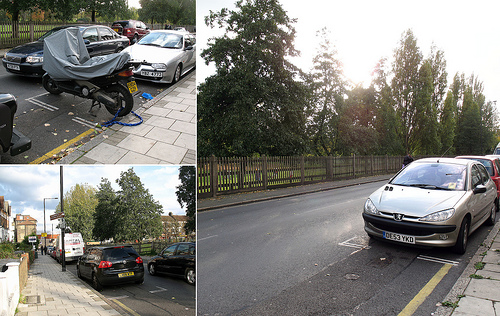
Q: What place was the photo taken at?
A: It was taken at the road.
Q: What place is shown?
A: It is a road.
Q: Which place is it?
A: It is a road.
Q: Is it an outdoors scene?
A: Yes, it is outdoors.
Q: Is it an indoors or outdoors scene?
A: It is outdoors.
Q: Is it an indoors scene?
A: No, it is outdoors.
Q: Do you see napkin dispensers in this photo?
A: No, there are no napkin dispensers.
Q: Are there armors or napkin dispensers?
A: No, there are no napkin dispensers or armors.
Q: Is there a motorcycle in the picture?
A: Yes, there is a motorcycle.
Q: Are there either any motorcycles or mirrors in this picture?
A: Yes, there is a motorcycle.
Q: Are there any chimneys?
A: No, there are no chimneys.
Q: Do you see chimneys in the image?
A: No, there are no chimneys.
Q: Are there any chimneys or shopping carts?
A: No, there are no chimneys or shopping carts.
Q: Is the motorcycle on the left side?
A: Yes, the motorcycle is on the left of the image.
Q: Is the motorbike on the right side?
A: No, the motorbike is on the left of the image.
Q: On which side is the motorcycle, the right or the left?
A: The motorcycle is on the left of the image.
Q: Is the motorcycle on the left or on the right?
A: The motorcycle is on the left of the image.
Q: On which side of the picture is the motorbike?
A: The motorbike is on the left of the image.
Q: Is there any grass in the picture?
A: Yes, there is grass.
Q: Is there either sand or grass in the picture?
A: Yes, there is grass.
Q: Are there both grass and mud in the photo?
A: No, there is grass but no mud.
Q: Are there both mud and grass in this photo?
A: No, there is grass but no mud.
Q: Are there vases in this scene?
A: No, there are no vases.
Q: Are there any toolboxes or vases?
A: No, there are no vases or toolboxes.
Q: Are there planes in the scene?
A: No, there are no planes.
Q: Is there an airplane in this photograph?
A: No, there are no airplanes.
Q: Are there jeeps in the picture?
A: No, there are no jeeps.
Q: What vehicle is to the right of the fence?
A: The vehicle is a car.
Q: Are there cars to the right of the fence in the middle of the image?
A: Yes, there is a car to the right of the fence.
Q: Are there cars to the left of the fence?
A: No, the car is to the right of the fence.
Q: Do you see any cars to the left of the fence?
A: No, the car is to the right of the fence.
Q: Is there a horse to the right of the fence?
A: No, there is a car to the right of the fence.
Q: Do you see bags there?
A: No, there are no bags.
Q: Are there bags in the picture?
A: No, there are no bags.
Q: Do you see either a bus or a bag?
A: No, there are no bags or buses.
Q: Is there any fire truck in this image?
A: No, there are no fire trucks.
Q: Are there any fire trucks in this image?
A: No, there are no fire trucks.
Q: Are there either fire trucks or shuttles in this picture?
A: No, there are no fire trucks or shuttles.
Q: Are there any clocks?
A: No, there are no clocks.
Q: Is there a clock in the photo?
A: No, there are no clocks.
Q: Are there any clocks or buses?
A: No, there are no clocks or buses.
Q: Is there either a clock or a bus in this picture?
A: No, there are no clocks or buses.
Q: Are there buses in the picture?
A: No, there are no buses.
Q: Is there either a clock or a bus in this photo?
A: No, there are no buses or clocks.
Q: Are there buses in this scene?
A: No, there are no buses.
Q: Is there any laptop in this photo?
A: No, there are no laptops.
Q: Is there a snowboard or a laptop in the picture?
A: No, there are no laptops or snowboards.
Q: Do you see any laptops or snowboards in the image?
A: No, there are no laptops or snowboards.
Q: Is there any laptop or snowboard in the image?
A: No, there are no laptops or snowboards.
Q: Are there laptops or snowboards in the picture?
A: No, there are no laptops or snowboards.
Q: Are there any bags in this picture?
A: No, there are no bags.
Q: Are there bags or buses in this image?
A: No, there are no bags or buses.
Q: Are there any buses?
A: No, there are no buses.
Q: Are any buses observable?
A: No, there are no buses.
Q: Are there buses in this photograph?
A: No, there are no buses.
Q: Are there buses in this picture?
A: No, there are no buses.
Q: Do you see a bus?
A: No, there are no buses.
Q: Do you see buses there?
A: No, there are no buses.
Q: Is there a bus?
A: No, there are no buses.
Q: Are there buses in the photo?
A: No, there are no buses.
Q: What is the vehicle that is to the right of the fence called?
A: The vehicle is a car.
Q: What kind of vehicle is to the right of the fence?
A: The vehicle is a car.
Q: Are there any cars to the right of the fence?
A: Yes, there is a car to the right of the fence.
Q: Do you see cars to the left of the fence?
A: No, the car is to the right of the fence.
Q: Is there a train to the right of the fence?
A: No, there is a car to the right of the fence.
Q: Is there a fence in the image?
A: Yes, there is a fence.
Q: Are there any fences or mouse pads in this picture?
A: Yes, there is a fence.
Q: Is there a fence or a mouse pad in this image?
A: Yes, there is a fence.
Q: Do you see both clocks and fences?
A: No, there is a fence but no clocks.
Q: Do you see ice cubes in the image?
A: No, there are no ice cubes.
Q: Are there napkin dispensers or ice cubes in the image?
A: No, there are no ice cubes or napkin dispensers.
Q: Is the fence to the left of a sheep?
A: No, the fence is to the left of the car.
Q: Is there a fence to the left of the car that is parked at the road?
A: Yes, there is a fence to the left of the car.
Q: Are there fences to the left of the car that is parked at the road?
A: Yes, there is a fence to the left of the car.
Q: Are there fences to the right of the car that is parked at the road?
A: No, the fence is to the left of the car.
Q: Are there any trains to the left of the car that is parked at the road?
A: No, there is a fence to the left of the car.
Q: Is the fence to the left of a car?
A: Yes, the fence is to the left of a car.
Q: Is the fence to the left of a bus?
A: No, the fence is to the left of a car.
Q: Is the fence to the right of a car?
A: No, the fence is to the left of a car.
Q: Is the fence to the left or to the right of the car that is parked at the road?
A: The fence is to the left of the car.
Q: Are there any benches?
A: No, there are no benches.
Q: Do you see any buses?
A: No, there are no buses.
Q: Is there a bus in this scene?
A: No, there are no buses.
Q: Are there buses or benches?
A: No, there are no buses or benches.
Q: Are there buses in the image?
A: No, there are no buses.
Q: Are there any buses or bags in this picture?
A: No, there are no buses or bags.